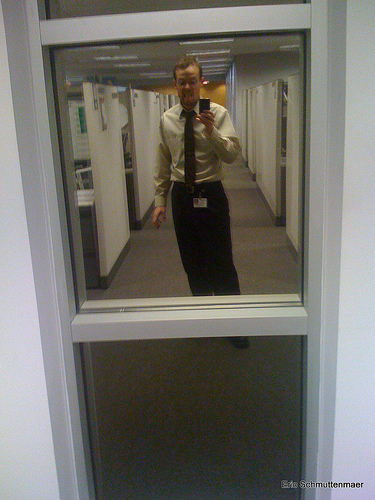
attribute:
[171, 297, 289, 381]
shoe — black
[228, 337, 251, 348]
shoe — man's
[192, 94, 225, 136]
phone — black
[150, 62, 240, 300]
man — selfie-taking, taking picture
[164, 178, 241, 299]
pants — dakr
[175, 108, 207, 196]
tie — black, for neck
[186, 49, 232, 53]
lighting — fluorescent, over head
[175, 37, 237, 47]
lighting — fluorescent, over head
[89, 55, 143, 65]
lighting — fluorescent, over head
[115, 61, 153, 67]
lighting — fluorescent, over head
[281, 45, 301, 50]
lighting — fluorescent, over head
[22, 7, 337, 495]
frame — double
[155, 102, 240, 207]
shirt — long sleeve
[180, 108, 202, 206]
tie — long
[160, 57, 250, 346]
male — business casual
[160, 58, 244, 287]
man — standing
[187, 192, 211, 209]
tag — name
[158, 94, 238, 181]
shirt — white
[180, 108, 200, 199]
tie — dark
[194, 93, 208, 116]
phone — square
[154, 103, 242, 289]
clothes — dress